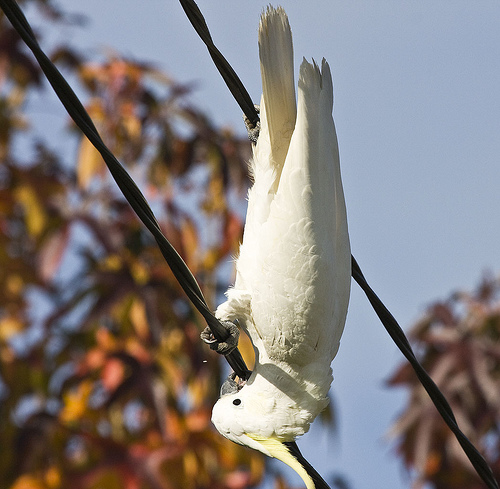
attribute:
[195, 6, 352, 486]
bird — hanging, white, upside-down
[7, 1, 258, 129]
wire — black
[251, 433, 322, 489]
feather — yellow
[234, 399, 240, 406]
eye — tiny, black, small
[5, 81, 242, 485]
tree — colorful, blurred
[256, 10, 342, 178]
tail feathers — white, long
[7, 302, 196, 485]
leaves — orange, yellow